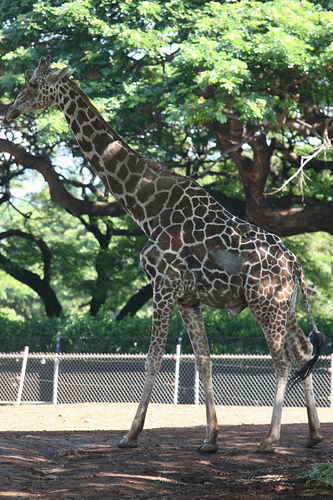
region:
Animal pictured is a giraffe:
[7, 46, 325, 457]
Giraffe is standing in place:
[3, 31, 327, 490]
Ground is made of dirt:
[9, 402, 327, 487]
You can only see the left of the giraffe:
[15, 52, 317, 479]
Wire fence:
[6, 348, 138, 399]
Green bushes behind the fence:
[11, 312, 146, 350]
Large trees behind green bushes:
[17, 165, 106, 338]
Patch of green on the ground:
[301, 452, 332, 484]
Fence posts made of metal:
[51, 348, 63, 405]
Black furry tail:
[284, 322, 324, 389]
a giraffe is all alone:
[15, 68, 308, 469]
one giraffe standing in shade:
[1, 50, 326, 453]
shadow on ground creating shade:
[1, 403, 330, 491]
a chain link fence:
[11, 345, 332, 413]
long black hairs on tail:
[298, 324, 332, 402]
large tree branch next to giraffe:
[16, 66, 324, 242]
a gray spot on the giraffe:
[205, 246, 246, 281]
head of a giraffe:
[8, 54, 80, 130]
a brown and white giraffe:
[5, 57, 320, 445]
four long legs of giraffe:
[100, 288, 331, 471]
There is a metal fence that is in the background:
[89, 338, 109, 403]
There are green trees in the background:
[74, 318, 92, 339]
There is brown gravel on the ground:
[64, 408, 73, 440]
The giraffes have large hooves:
[116, 425, 151, 476]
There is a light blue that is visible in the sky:
[24, 174, 35, 202]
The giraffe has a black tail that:
[308, 325, 330, 384]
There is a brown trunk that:
[24, 283, 69, 324]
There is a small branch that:
[299, 140, 316, 182]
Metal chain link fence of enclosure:
[2, 342, 330, 411]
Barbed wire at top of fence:
[4, 329, 332, 355]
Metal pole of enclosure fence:
[44, 329, 70, 403]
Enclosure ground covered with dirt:
[2, 404, 329, 494]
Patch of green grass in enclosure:
[305, 459, 332, 488]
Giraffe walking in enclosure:
[4, 54, 327, 452]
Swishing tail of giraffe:
[285, 256, 327, 399]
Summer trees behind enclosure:
[9, 4, 329, 325]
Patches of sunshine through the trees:
[6, 119, 110, 220]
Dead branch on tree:
[268, 122, 331, 204]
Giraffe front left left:
[119, 274, 183, 454]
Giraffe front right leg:
[174, 304, 223, 459]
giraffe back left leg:
[242, 284, 290, 455]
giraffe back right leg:
[296, 308, 329, 446]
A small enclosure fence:
[0, 349, 332, 406]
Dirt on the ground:
[17, 409, 111, 488]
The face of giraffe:
[4, 57, 51, 128]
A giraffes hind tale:
[287, 265, 326, 400]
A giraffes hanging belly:
[191, 263, 244, 308]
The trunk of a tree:
[0, 255, 69, 314]